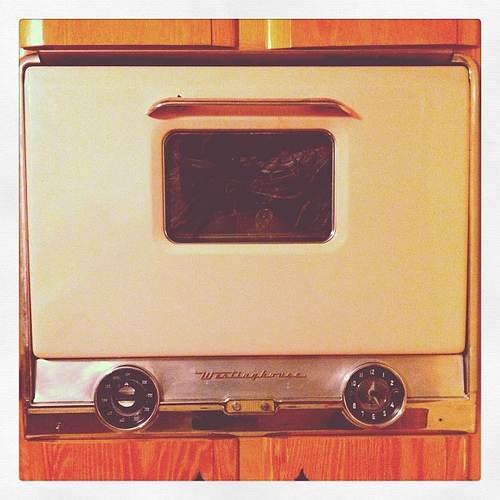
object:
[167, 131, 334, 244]
part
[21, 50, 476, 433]
stove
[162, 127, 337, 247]
clear part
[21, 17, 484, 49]
wood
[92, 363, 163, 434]
knob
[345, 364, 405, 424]
clock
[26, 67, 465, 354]
door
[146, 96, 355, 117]
handle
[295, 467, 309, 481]
point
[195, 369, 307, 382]
name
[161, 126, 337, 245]
window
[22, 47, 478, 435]
oven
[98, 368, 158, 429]
dial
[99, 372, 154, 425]
numbers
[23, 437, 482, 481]
cabinet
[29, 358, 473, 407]
part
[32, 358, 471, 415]
base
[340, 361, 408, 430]
knob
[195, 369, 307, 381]
logo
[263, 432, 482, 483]
cabinet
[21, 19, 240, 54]
cabinet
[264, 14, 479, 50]
cabinet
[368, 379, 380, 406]
hands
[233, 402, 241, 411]
bolt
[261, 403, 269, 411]
bolt